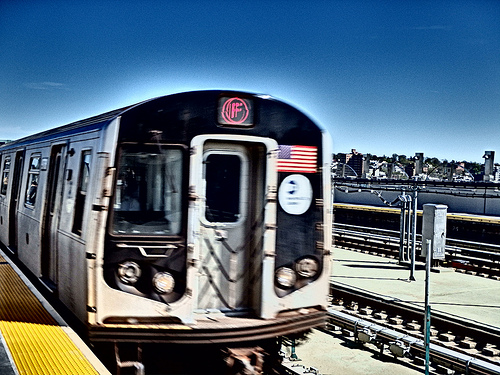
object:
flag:
[273, 143, 321, 170]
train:
[1, 89, 335, 348]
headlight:
[294, 257, 320, 278]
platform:
[1, 250, 113, 375]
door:
[36, 135, 70, 294]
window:
[69, 147, 94, 239]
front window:
[105, 139, 187, 236]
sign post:
[420, 236, 435, 345]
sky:
[1, 1, 500, 162]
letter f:
[231, 103, 244, 120]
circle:
[221, 98, 251, 126]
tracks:
[325, 280, 499, 375]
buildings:
[337, 153, 365, 179]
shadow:
[1, 254, 71, 327]